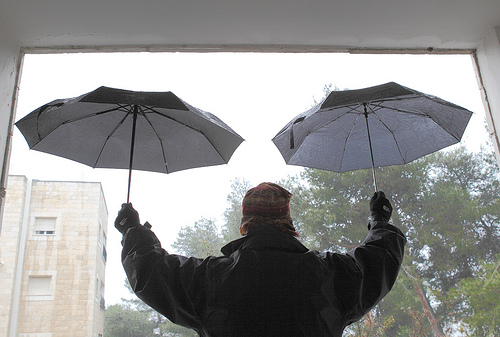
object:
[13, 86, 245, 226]
umbrella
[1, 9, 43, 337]
left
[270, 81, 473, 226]
umbrella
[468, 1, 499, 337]
right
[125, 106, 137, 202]
pole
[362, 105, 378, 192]
pole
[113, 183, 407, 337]
person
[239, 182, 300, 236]
hat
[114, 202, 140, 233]
glove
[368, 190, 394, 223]
glove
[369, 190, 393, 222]
right hand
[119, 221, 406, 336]
jacket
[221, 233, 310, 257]
collar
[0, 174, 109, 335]
building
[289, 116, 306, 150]
strap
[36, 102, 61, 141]
strap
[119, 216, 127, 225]
logo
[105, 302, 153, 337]
tree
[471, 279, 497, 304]
leaves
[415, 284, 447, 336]
trunk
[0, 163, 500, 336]
background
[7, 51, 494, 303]
sky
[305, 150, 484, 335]
tree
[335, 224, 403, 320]
arm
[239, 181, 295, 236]
head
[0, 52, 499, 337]
doorway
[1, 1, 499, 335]
building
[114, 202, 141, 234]
hand